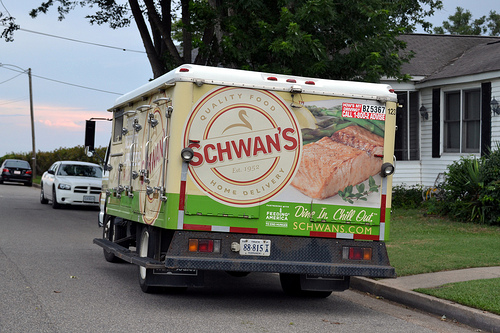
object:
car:
[0, 158, 34, 187]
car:
[39, 160, 104, 209]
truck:
[89, 64, 403, 301]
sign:
[340, 101, 388, 121]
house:
[417, 42, 499, 207]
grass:
[386, 208, 500, 315]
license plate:
[238, 238, 270, 256]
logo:
[183, 86, 303, 209]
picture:
[289, 99, 386, 208]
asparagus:
[318, 109, 385, 138]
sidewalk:
[376, 265, 500, 291]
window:
[443, 86, 481, 154]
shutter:
[430, 87, 442, 158]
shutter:
[480, 82, 491, 160]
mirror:
[83, 120, 96, 157]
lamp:
[419, 103, 428, 121]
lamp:
[489, 96, 499, 114]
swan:
[221, 109, 254, 134]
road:
[1, 179, 496, 333]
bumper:
[164, 231, 396, 278]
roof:
[330, 33, 500, 77]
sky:
[0, 1, 499, 158]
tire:
[104, 216, 128, 263]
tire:
[136, 224, 166, 295]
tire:
[279, 274, 333, 300]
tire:
[39, 182, 49, 205]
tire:
[52, 187, 60, 209]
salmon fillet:
[290, 135, 383, 200]